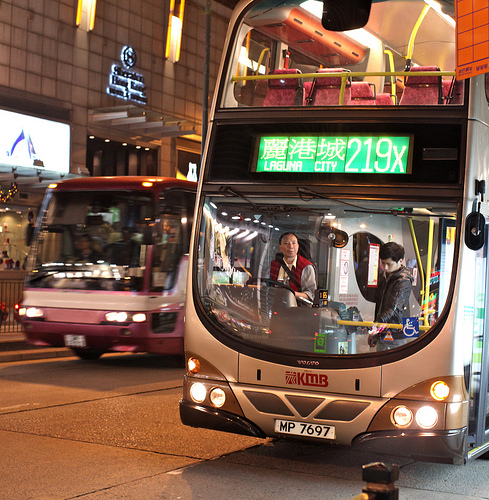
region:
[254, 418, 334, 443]
white license plate with black letters and numbers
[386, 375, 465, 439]
three lights on a bus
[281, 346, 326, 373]
silver letters trhat say volvo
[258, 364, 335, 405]
red letters that say kmb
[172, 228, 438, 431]
front of a bus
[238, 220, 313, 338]
a bus driver with seat belt on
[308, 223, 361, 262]
rear view mirror of bus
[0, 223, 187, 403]
pink and white bus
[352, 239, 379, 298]
red and white paper on window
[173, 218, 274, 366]
reflection in bus window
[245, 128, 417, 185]
Electronic sign on front of bus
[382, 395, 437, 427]
Headlights on front of passenger bus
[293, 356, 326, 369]
Medallion from manufacturer of passenger bus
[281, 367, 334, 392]
Logo of bus company on front of bus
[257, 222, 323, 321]
Bus driver driving passenger bus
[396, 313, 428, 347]
Handicap accessible sticker in windshield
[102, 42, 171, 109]
Illuminated sign for a hotel on the wall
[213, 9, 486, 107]
Top level of a double-decker bus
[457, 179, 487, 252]
Rearview mirror for passenger bus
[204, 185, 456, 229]
Windshield wipers on a passenger bus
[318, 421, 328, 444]
NUMBERS 7697 IS WRITTEN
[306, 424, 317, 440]
NUMBERS 7697 IS WRITTEN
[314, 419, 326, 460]
NUMBERS 7697 IS WRITTEN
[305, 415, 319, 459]
NUMBERS 7697 IS WRITTEN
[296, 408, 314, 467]
NUMBERS 7697 IS WRITTEN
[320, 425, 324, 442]
NUMBERS 7697 IS WRITTEN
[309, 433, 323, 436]
NUMBERS 7697 IS WRITTEN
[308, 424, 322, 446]
NUMBERS 7697 IS WRITTEN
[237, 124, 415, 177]
The route name and number of this bus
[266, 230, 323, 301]
A male driver of this bus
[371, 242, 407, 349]
A male bus rider in a black jacket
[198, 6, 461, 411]
A double-decker bus in Hong Kong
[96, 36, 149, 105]
A store sign lit at night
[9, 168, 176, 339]
A medium size bus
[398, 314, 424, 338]
A sign shown disability equipped in this bus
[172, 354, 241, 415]
The right three front lights of this bus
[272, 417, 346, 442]
The registration plate of this bus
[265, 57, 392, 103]
A number of empty bus seats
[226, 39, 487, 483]
double decker bus in photograph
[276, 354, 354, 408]
red lettering on front of bus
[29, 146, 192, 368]
pink colored bus on street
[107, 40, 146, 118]
lighted black sign above building entrance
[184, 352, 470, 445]
headlights on black bus turned on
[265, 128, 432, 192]
green light on bus with white lighted lettering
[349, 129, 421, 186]
green light says 219x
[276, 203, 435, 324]
two people in front of bus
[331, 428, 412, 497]
fire hydrant is black and yellow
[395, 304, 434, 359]
blue handicapped sticker on bus window